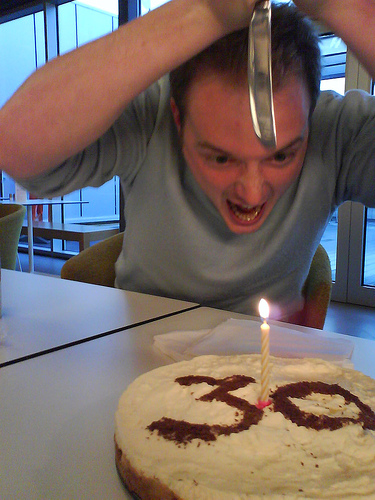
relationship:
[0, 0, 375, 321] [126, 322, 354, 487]
man stabs cake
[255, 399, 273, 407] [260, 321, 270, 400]
piece holds candle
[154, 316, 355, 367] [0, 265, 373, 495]
napkin on table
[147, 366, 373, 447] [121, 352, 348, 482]
number on cake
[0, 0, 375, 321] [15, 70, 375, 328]
man wearing gray shirt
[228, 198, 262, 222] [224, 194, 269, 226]
teeth in mouth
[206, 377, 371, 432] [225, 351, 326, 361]
brown frosting on white frosting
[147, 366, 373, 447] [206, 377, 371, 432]
number written with brown frosting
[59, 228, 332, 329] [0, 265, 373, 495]
chair next to table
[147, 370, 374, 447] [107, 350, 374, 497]
number on cake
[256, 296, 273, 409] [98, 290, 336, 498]
candle on cake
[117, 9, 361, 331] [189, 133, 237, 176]
man has eye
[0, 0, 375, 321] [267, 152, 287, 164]
man has eye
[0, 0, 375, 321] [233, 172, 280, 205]
man has nose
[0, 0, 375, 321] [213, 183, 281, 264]
man has mouth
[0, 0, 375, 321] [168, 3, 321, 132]
man has hair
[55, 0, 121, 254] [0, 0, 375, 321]
window behind man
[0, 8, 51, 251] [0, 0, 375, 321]
window behind man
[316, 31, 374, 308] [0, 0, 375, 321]
door behind man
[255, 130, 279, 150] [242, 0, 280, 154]
tip on knife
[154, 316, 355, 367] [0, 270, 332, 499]
napkin laying on table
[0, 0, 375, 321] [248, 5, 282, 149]
man holding knife